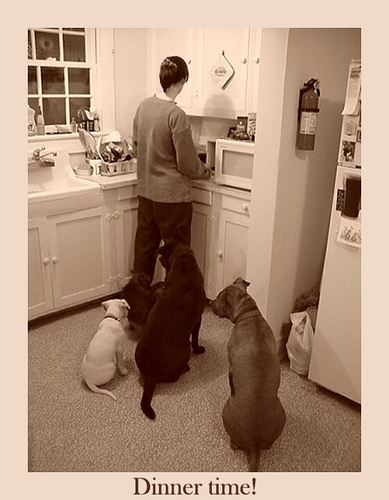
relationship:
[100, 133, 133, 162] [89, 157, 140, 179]
dishes inside drainer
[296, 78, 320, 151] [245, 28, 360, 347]
fire extinguisher hanging on wall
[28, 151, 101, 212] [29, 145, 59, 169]
sink with faucet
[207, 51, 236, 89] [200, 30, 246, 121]
pot holder hanging on cabinet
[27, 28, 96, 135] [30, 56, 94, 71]
window with panes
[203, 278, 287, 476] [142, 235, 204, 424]
dog next to dog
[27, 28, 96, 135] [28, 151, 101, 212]
window above sink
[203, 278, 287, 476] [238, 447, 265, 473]
dog has tail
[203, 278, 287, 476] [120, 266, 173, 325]
dog next to cat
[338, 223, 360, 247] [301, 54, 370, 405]
paper on front of refrigerator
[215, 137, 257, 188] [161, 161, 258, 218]
microwave on top of counter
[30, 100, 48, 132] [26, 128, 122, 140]
dish soup on top of window sill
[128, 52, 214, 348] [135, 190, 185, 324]
woman wearing jeans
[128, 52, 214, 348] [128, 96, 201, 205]
woman wearing shirt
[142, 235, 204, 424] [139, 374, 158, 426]
dog has tail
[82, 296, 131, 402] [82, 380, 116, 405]
dog has tail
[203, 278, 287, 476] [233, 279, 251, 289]
dog has ear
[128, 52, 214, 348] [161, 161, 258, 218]
woman standing in front of counter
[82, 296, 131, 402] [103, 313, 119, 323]
dog wearing collar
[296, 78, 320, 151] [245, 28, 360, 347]
fire extinguisher on side of wall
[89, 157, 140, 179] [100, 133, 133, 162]
drainer holding dishes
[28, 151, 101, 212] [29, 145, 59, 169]
sink has faucet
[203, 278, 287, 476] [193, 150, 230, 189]
dog waiting for food